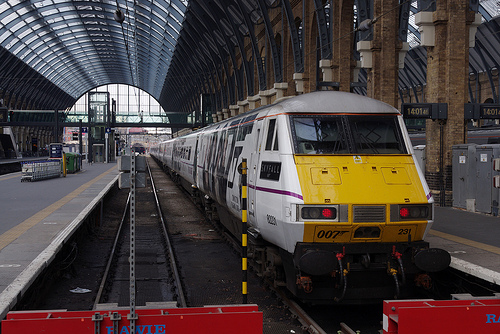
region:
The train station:
[128, 98, 331, 215]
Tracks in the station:
[106, 153, 218, 331]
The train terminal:
[41, 56, 163, 220]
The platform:
[65, 157, 112, 197]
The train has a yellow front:
[271, 121, 471, 306]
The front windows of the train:
[289, 88, 412, 158]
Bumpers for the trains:
[34, 291, 109, 326]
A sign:
[399, 84, 481, 148]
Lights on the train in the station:
[300, 212, 341, 224]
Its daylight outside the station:
[64, 92, 216, 175]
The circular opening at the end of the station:
[60, 83, 173, 145]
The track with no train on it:
[93, 145, 188, 309]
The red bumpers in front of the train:
[5, 291, 497, 332]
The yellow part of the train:
[291, 153, 427, 253]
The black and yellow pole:
[235, 157, 254, 306]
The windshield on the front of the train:
[284, 111, 411, 158]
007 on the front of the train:
[310, 223, 352, 243]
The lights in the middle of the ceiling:
[0, 2, 188, 98]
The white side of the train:
[137, 105, 304, 249]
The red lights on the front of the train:
[320, 204, 410, 221]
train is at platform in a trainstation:
[0, 7, 489, 304]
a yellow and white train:
[130, 96, 451, 291]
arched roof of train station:
[5, 0, 182, 109]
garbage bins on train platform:
[60, 150, 87, 175]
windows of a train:
[290, 111, 413, 156]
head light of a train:
[294, 203, 340, 223]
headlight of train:
[389, 199, 436, 222]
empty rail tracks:
[103, 150, 174, 325]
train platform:
[0, 156, 125, 314]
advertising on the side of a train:
[254, 157, 281, 185]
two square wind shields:
[269, 98, 428, 168]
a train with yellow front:
[266, 82, 452, 262]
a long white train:
[119, 91, 444, 257]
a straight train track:
[114, 139, 187, 320]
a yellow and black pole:
[225, 149, 266, 304]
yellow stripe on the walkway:
[5, 176, 89, 248]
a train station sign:
[398, 86, 456, 140]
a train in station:
[68, 51, 452, 321]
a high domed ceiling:
[15, 0, 228, 170]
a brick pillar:
[414, 13, 469, 143]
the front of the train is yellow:
[244, 87, 453, 277]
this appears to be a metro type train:
[156, 10, 441, 255]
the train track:
[116, 135, 186, 314]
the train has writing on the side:
[171, 110, 259, 237]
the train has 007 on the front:
[290, 212, 463, 259]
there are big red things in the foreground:
[61, 287, 281, 332]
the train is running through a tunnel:
[18, 2, 458, 179]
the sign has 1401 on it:
[400, 98, 451, 124]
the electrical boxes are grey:
[440, 133, 499, 227]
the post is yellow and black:
[221, 150, 279, 305]